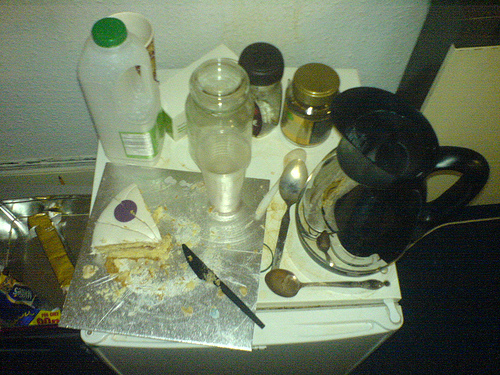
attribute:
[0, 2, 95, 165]
wall — white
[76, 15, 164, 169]
bottle — plastic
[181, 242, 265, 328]
knife — black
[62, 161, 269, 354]
tray — silver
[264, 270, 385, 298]
spoon — metal, silver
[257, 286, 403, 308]
fridge — white, closed, messy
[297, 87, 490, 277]
kettle — black, shiny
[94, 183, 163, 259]
cake — left-over, leftover, cut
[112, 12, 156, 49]
cup — empty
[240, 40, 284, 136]
bottle — plastic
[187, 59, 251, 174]
jar — glass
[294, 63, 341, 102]
lid — golden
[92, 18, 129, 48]
cap — green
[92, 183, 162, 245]
frosting — white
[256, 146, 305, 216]
spoon — plastic